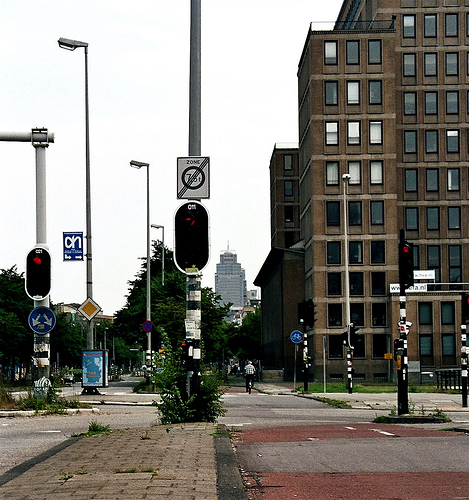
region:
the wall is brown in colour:
[307, 27, 466, 287]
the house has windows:
[300, 31, 468, 273]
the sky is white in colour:
[111, 20, 177, 135]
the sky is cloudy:
[216, 146, 254, 220]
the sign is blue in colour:
[282, 326, 304, 348]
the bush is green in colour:
[135, 356, 226, 414]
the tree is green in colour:
[2, 268, 28, 343]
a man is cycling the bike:
[244, 341, 259, 403]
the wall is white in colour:
[215, 243, 247, 298]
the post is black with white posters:
[174, 276, 207, 379]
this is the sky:
[102, 186, 134, 261]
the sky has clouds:
[219, 168, 254, 223]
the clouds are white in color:
[214, 183, 245, 221]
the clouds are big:
[98, 180, 142, 245]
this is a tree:
[119, 242, 232, 378]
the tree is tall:
[149, 243, 171, 346]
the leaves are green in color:
[206, 299, 224, 339]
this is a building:
[271, 163, 450, 381]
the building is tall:
[214, 242, 244, 304]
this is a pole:
[33, 158, 51, 245]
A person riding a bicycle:
[242, 359, 256, 393]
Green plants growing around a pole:
[146, 323, 227, 426]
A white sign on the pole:
[175, 152, 211, 198]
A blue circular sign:
[29, 304, 55, 335]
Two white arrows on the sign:
[31, 313, 54, 328]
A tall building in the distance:
[212, 250, 249, 323]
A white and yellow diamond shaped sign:
[75, 296, 101, 320]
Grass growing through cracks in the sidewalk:
[110, 463, 156, 474]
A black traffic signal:
[169, 199, 210, 276]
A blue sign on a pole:
[287, 327, 305, 393]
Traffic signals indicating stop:
[18, 205, 415, 300]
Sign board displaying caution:
[172, 147, 222, 195]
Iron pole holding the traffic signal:
[174, 6, 227, 423]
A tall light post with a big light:
[56, 30, 112, 403]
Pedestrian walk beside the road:
[0, 435, 468, 498]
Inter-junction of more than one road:
[90, 376, 410, 455]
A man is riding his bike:
[244, 349, 266, 397]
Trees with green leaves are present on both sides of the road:
[135, 246, 224, 393]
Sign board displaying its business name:
[381, 259, 455, 378]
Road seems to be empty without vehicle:
[0, 396, 468, 481]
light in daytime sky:
[0, 0, 346, 305]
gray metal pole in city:
[183, 1, 207, 398]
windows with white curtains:
[325, 159, 384, 185]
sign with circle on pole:
[175, 154, 211, 200]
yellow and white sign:
[79, 296, 101, 320]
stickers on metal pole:
[184, 286, 203, 389]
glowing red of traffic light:
[24, 247, 51, 299]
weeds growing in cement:
[63, 423, 159, 479]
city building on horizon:
[213, 251, 253, 315]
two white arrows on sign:
[28, 306, 54, 335]